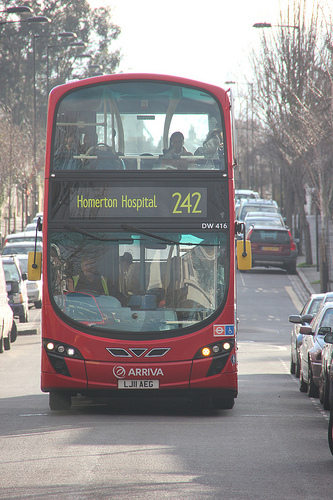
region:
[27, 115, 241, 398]
A double decker bus on the street.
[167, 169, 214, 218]
The bus has a number 242 on it.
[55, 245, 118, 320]
The driver of the bus is on the left side.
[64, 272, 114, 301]
The driver is wearing a yellow vest.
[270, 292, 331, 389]
Cars parked on the side of the street.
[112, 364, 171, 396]
The car has a license plate in the front.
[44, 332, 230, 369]
The headlights of the bus are on.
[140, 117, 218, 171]
People are sitting on the upper level of the bus.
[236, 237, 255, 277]
The side mirror on the bus is yellow.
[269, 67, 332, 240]
Trees with no leaves on the sidewalk.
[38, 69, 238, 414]
the bus is red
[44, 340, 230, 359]
the bus has lights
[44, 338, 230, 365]
the lights on the bus are on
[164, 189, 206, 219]
the number on the bus is 242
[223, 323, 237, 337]
the bus has a handicap symbol on the front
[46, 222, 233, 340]
the bus has a very large windshield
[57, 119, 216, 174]
the bus has passengers on the upper level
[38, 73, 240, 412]
the bus has two levels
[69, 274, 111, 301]
the bus driver is wearing a yellow vest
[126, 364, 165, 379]
the front of the bus says arriva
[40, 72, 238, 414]
red double-tall bus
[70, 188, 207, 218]
electronic sign with green letters reading "Homerton Hospital"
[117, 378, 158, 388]
short and wide vehicle license plate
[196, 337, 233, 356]
traffic nightlights for traveling in low-light conditions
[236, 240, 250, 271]
yellow rear-view mirror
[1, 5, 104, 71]
six roadlights positioned close to each other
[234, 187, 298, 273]
five parked vehicles of various sizes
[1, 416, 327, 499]
asphalt for driving safely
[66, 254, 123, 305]
male passenger clad in safety vest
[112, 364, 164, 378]
name of the bus' manufacturer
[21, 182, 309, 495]
picture taken outdoors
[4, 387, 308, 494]
picture taken from the street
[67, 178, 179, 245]
a bus says Homerton Hospital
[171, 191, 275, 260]
the number on the bus sign is 242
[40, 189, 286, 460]
the make of the bus is arriva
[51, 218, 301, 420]
the bus is red and black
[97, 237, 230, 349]
the bus has passengers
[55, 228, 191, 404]
a driver is driving the bus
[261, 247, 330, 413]
cars are parked on the side of the street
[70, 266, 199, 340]
the bus driver is wearing a yellow vest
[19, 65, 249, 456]
Double decker bus driving in a city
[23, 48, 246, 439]
Big bus carrying many passengers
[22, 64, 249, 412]
Bus taking workers back home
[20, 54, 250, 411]
Bus on its route through the city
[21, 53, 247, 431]
Bus taking people to their destination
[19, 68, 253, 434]
Bus with people riding on two levels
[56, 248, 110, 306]
Driver of a big bus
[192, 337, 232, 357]
Headlights for a big bus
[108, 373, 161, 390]
License plate of a big bus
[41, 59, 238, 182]
Top of a double decker bus